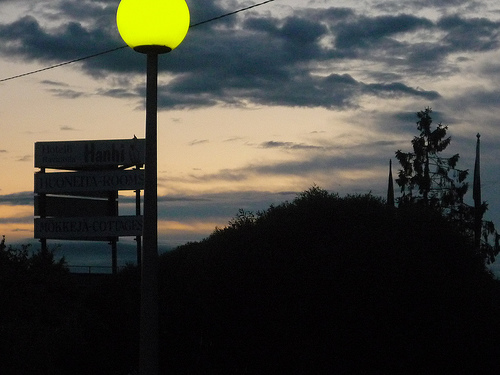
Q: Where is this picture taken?
A: Outside it is getting dark.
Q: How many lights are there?
A: One.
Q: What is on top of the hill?
A: A tree.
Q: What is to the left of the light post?
A: Signs.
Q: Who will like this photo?
A: A person who loves sunsets and great landscapes.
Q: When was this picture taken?
A: Sunset.